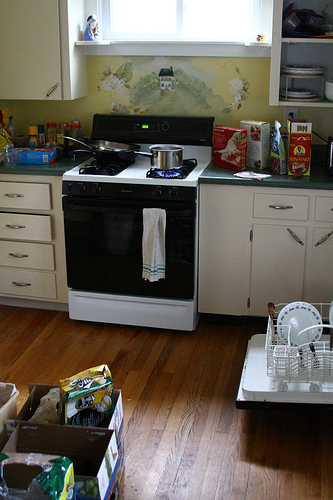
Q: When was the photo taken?
A: Daytime.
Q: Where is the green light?
A: Green.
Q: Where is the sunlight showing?
A: Window.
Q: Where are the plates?
A: Dishwasher basket.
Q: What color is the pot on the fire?
A: Silver.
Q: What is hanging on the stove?
A: Towel.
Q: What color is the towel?
A: White.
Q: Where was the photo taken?
A: In a kitchen.